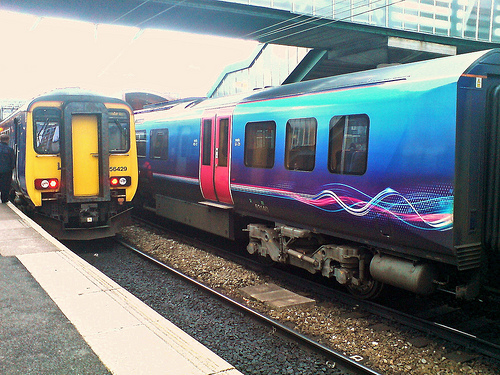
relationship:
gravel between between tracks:
[150, 241, 308, 337] [71, 239, 381, 375]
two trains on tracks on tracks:
[9, 54, 497, 332] [107, 226, 373, 373]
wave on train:
[215, 158, 479, 246] [117, 94, 467, 238]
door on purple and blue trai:
[214, 113, 234, 206] [132, 47, 500, 302]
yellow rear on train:
[25, 95, 142, 212] [13, 97, 130, 222]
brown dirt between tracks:
[120, 221, 279, 312] [89, 231, 451, 366]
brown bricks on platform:
[58, 229, 281, 364] [0, 225, 221, 368]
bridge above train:
[0, 0, 499, 68] [135, 87, 465, 248]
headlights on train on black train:
[29, 169, 71, 198] [0, 94, 139, 242]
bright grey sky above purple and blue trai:
[11, 21, 255, 113] [132, 47, 500, 302]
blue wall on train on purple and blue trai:
[165, 91, 469, 248] [132, 47, 500, 302]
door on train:
[214, 113, 234, 206] [135, 97, 453, 233]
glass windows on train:
[238, 110, 285, 192] [145, 95, 497, 199]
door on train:
[198, 114, 218, 202] [7, 102, 139, 194]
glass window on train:
[283, 113, 336, 181] [9, 90, 141, 209]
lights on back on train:
[119, 177, 127, 185] [21, 101, 144, 211]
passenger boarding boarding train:
[0, 129, 28, 215] [12, 96, 137, 204]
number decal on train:
[107, 162, 134, 178] [17, 95, 136, 218]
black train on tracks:
[0, 94, 139, 242] [74, 192, 396, 348]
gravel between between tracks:
[117, 212, 215, 278] [94, 184, 390, 374]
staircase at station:
[242, 0, 474, 56] [1, 2, 498, 373]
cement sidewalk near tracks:
[0, 204, 242, 375] [128, 249, 366, 373]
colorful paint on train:
[230, 176, 457, 235] [96, 54, 484, 358]